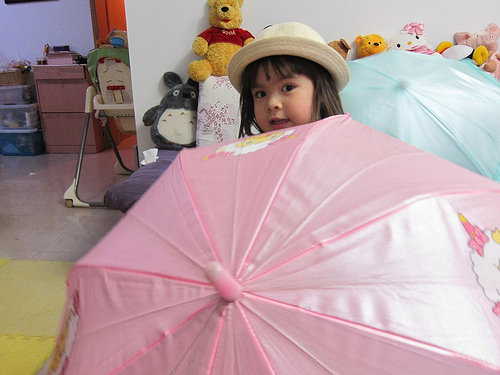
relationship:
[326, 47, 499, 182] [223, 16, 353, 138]
umbrella behind girl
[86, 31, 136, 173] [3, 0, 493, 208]
highchair in background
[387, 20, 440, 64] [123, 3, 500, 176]
hello kitty against wall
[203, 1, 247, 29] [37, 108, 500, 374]
head behind umbrella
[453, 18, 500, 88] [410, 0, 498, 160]
animal in top right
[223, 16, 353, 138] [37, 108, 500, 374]
girl with umbrella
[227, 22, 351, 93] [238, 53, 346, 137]
hat on head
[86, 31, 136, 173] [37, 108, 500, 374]
highchair in room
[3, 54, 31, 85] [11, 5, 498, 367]
box in room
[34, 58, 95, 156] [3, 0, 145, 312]
dresser in corner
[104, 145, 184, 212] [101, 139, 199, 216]
covering for bed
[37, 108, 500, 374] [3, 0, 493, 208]
umbrella in background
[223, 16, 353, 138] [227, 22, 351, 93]
girl wearing hat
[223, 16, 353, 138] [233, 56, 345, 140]
girl with hair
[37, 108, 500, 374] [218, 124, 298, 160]
umbrella with sheep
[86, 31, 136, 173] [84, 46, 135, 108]
highchair with seat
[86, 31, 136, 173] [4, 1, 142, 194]
highchair in back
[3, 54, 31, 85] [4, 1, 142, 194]
box in back